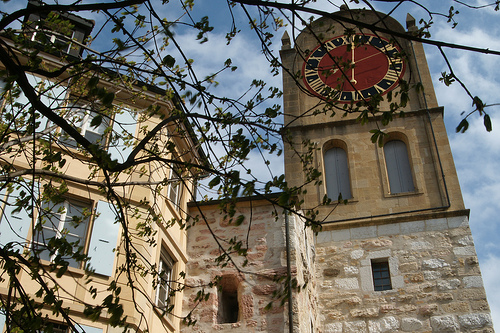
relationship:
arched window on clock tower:
[382, 131, 414, 194] [273, 20, 495, 331]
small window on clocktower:
[366, 251, 396, 296] [264, 11, 486, 331]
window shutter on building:
[86, 201, 122, 277] [0, 0, 499, 333]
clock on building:
[246, 9, 456, 231] [0, 0, 499, 333]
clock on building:
[301, 33, 406, 103] [280, 5, 492, 332]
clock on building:
[301, 33, 406, 103] [0, 0, 499, 333]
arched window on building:
[322, 138, 353, 201] [0, 0, 499, 333]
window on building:
[215, 269, 243, 326] [173, 1, 494, 329]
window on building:
[360, 247, 402, 301] [0, 0, 499, 333]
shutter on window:
[0, 152, 145, 284] [27, 181, 108, 265]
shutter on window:
[82, 201, 173, 285] [27, 184, 102, 258]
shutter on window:
[2, 71, 72, 154] [50, 73, 123, 160]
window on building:
[370, 257, 393, 291] [280, 5, 492, 332]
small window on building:
[369, 257, 392, 291] [0, 0, 499, 333]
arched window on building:
[382, 131, 414, 194] [0, 0, 499, 333]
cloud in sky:
[0, 0, 500, 331] [1, 0, 498, 332]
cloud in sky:
[192, 110, 283, 197] [1, 0, 498, 332]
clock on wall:
[301, 33, 406, 103] [265, 0, 463, 168]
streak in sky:
[89, 10, 277, 52] [1, 0, 498, 332]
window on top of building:
[31, 16, 76, 54] [0, 0, 499, 333]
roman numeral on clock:
[351, 87, 365, 103] [290, 27, 408, 103]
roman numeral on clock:
[382, 66, 402, 82] [290, 27, 408, 103]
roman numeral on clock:
[322, 37, 338, 50] [290, 27, 408, 103]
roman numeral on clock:
[381, 40, 396, 52] [290, 27, 408, 103]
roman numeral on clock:
[302, 66, 321, 76] [290, 27, 408, 103]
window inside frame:
[370, 257, 393, 291] [362, 248, 399, 296]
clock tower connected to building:
[280, 5, 495, 333] [0, 1, 310, 331]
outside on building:
[2, 7, 449, 331] [269, 37, 492, 331]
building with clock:
[0, 0, 499, 333] [296, 27, 408, 111]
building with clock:
[50, 20, 498, 307] [288, 19, 414, 121]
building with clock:
[0, 0, 499, 333] [301, 33, 406, 103]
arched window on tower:
[372, 122, 426, 204] [273, 6, 499, 331]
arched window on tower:
[313, 130, 360, 208] [273, 6, 499, 331]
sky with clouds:
[447, 12, 497, 98] [108, 2, 484, 211]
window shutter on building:
[86, 197, 121, 279] [0, 0, 499, 333]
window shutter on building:
[4, 175, 48, 256] [0, 0, 499, 333]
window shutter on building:
[103, 100, 138, 162] [0, 0, 499, 333]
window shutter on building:
[32, 75, 68, 144] [0, 0, 499, 333]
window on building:
[370, 257, 393, 291] [0, 0, 499, 333]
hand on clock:
[345, 37, 362, 98] [294, 8, 437, 111]